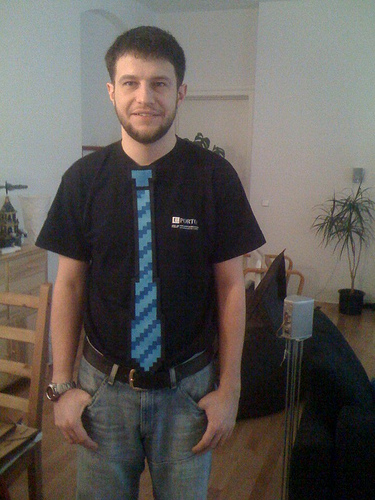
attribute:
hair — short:
[95, 30, 189, 130]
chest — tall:
[1, 241, 51, 387]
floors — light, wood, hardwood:
[210, 421, 299, 499]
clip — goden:
[126, 368, 147, 390]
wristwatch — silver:
[40, 377, 76, 403]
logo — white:
[165, 203, 201, 236]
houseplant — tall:
[307, 172, 373, 318]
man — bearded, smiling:
[42, 22, 253, 492]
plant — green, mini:
[309, 171, 374, 292]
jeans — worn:
[55, 333, 226, 498]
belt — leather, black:
[123, 368, 162, 400]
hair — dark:
[120, 33, 165, 50]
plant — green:
[315, 187, 373, 320]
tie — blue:
[123, 167, 169, 377]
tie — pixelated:
[131, 167, 165, 372]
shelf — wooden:
[1, 241, 48, 395]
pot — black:
[337, 288, 364, 316]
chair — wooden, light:
[0, 282, 53, 499]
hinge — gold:
[128, 366, 148, 392]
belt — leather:
[80, 336, 215, 389]